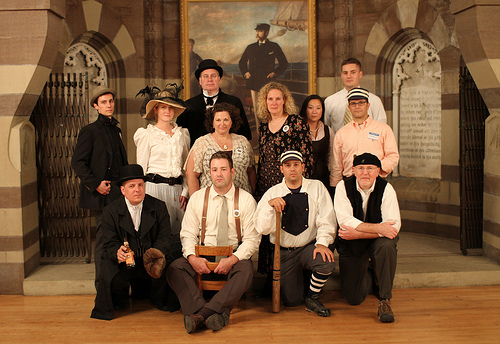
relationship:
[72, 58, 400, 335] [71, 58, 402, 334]
group of group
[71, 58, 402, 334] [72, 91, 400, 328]
group are in clothes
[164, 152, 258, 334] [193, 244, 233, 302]
man sitting on chair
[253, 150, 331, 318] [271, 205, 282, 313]
man leaning on bat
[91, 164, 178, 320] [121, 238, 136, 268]
man holding beer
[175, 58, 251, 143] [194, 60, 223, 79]
man wearing hat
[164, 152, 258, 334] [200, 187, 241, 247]
man wearing suspenders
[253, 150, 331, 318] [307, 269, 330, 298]
man wearing socks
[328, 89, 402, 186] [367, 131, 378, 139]
man has a name tag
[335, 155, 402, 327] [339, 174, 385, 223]
man wearing vest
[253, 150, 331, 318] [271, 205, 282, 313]
man holding bat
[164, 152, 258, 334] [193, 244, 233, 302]
man on chair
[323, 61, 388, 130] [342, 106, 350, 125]
man has tie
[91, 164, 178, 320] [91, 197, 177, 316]
man wearing coat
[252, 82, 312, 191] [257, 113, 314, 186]
woman wearing dress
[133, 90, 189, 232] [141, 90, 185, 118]
woman wearing hat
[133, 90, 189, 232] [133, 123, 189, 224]
woman wearing dress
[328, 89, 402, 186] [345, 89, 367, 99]
man wearing hat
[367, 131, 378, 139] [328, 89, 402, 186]
name tag on man